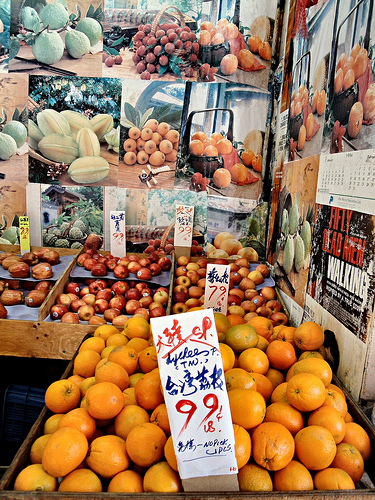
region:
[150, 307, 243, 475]
a sign with blue and white writing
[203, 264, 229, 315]
a sign with blue and white writing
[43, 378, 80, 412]
an orange is in a box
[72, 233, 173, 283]
fruit are in a crate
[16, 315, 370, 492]
a box filled with oranges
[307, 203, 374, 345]
a black poster on a wall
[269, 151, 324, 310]
a poster is on a wall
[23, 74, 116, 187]
a poster showing fruit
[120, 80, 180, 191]
a poster showing fruit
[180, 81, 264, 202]
a poster showing fruit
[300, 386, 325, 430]
These are oranges here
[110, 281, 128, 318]
The fruits that are available are apples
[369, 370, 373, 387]
The color of the wall is off-white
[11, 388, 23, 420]
The container available here is blue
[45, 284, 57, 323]
There are some wooden dividers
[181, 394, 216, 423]
These oranges are 99 cents a pound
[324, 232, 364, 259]
There is a sign that reads "Dead Men"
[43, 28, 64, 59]
There are green pears that are in the poster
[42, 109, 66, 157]
There are some starfruit that are available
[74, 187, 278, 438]
Jackson Mingus is the one who took the photo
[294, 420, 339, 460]
orange in a box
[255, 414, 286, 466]
orange in a box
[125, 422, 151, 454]
orange in a box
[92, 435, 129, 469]
orange in a box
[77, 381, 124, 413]
orange in a box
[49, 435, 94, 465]
orange in a box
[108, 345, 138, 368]
orange in a box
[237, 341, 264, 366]
orange in a box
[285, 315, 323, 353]
orange in a box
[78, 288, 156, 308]
apples in a box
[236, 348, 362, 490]
pile of oranges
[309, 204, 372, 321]
sign for fifty dead men walking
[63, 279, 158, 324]
apples for sale in bin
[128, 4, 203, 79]
wicker basket with grapes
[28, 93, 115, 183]
small pile of star fruit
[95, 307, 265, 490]
bin of oranges for sale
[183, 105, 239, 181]
dark wicker baskets with oranges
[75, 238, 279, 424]
fruit for sale at stand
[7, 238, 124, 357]
wooden stand with fruit for sale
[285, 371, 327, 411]
one ripe orange with stem end forward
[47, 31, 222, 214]
pictures of fruit on the wall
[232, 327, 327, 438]
green and orange oranges for sale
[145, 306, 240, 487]
blue and red writing on white signs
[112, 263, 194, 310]
apples on blue trays in wood crates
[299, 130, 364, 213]
white and black printed calendar on wall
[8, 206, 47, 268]
bright yellow sign for the apples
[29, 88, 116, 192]
picture of melons on wood table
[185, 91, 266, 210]
picture of oranges in a basket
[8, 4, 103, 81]
pictures of green pears on wall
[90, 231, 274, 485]
oranges and apples for sale